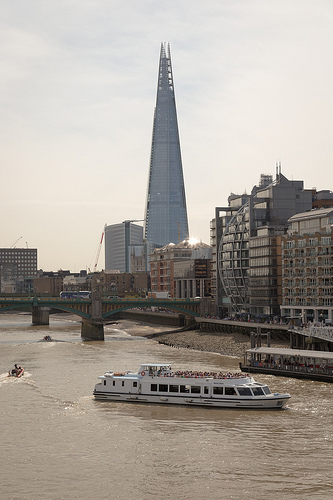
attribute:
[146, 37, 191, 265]
building — large, skyscraper, cone shaped, pyramid shaped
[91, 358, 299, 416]
ship — white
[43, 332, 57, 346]
boat — small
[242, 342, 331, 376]
boat — large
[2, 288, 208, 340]
bridge — green, brown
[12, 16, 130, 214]
sky — blue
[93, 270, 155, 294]
building — brown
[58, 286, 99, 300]
bus — blue, white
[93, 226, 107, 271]
crane — red, white